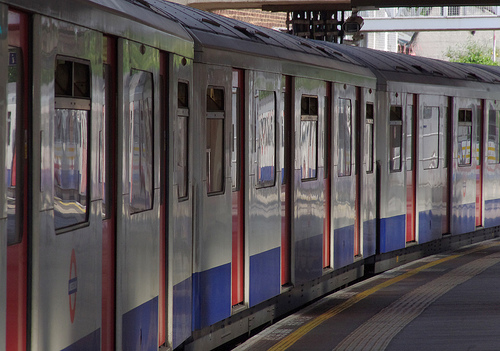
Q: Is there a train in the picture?
A: Yes, there is a train.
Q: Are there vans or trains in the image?
A: Yes, there is a train.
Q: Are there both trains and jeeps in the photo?
A: No, there is a train but no jeeps.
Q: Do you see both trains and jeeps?
A: No, there is a train but no jeeps.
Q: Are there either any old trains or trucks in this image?
A: Yes, there is an old train.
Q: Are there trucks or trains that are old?
A: Yes, the train is old.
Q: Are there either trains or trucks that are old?
A: Yes, the train is old.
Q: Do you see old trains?
A: Yes, there is an old train.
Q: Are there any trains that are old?
A: Yes, there is a train that is old.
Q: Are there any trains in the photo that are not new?
A: Yes, there is a old train.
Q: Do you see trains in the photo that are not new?
A: Yes, there is a old train.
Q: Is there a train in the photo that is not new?
A: Yes, there is a old train.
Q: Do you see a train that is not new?
A: Yes, there is a old train.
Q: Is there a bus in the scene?
A: No, there are no buses.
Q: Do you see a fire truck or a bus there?
A: No, there are no buses or fire trucks.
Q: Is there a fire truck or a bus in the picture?
A: No, there are no buses or fire trucks.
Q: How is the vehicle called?
A: The vehicle is a train.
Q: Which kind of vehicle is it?
A: The vehicle is a train.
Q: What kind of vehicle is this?
A: This is a train.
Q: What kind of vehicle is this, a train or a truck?
A: This is a train.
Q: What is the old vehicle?
A: The vehicle is a train.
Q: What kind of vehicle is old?
A: The vehicle is a train.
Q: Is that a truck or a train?
A: That is a train.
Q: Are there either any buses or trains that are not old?
A: No, there is a train but it is old.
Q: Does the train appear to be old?
A: Yes, the train is old.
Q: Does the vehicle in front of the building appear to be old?
A: Yes, the train is old.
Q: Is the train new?
A: No, the train is old.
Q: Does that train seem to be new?
A: No, the train is old.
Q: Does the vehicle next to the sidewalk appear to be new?
A: No, the train is old.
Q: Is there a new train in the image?
A: No, there is a train but it is old.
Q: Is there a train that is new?
A: No, there is a train but it is old.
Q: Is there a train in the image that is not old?
A: No, there is a train but it is old.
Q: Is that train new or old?
A: The train is old.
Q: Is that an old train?
A: Yes, that is an old train.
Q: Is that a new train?
A: No, that is an old train.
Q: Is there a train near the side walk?
A: Yes, there is a train near the side walk.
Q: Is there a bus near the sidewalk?
A: No, there is a train near the sidewalk.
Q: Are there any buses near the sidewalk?
A: No, there is a train near the sidewalk.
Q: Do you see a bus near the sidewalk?
A: No, there is a train near the sidewalk.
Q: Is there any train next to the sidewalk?
A: Yes, there is a train next to the sidewalk.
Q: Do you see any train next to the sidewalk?
A: Yes, there is a train next to the sidewalk.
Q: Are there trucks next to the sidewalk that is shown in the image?
A: No, there is a train next to the sidewalk.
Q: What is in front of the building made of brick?
A: The train is in front of the building.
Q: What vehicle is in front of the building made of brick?
A: The vehicle is a train.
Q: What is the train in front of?
A: The train is in front of the building.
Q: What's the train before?
A: The train is in front of the building.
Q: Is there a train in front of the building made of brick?
A: Yes, there is a train in front of the building.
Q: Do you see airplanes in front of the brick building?
A: No, there is a train in front of the building.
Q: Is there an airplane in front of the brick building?
A: No, there is a train in front of the building.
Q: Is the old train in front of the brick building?
A: Yes, the train is in front of the building.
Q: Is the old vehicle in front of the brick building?
A: Yes, the train is in front of the building.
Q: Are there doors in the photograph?
A: Yes, there is a door.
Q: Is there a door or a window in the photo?
A: Yes, there is a door.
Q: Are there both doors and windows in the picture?
A: Yes, there are both a door and a window.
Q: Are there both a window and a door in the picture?
A: Yes, there are both a door and a window.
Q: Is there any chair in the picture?
A: No, there are no chairs.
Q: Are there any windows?
A: Yes, there is a window.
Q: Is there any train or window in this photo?
A: Yes, there is a window.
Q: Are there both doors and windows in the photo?
A: Yes, there are both a window and a door.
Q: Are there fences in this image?
A: No, there are no fences.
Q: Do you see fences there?
A: No, there are no fences.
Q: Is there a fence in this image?
A: No, there are no fences.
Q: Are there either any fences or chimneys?
A: No, there are no fences or chimneys.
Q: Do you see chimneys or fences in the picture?
A: No, there are no fences or chimneys.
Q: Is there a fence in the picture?
A: No, there are no fences.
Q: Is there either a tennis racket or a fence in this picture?
A: No, there are no fences or rackets.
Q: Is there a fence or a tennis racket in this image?
A: No, there are no fences or rackets.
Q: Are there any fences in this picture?
A: No, there are no fences.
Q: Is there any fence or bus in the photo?
A: No, there are no fences or buses.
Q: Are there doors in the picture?
A: Yes, there is a door.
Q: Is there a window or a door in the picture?
A: Yes, there is a door.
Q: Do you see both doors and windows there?
A: Yes, there are both a door and a window.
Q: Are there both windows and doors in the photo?
A: Yes, there are both a door and a window.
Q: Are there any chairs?
A: No, there are no chairs.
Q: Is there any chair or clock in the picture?
A: No, there are no chairs or clocks.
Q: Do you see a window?
A: Yes, there is a window.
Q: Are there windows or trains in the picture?
A: Yes, there is a window.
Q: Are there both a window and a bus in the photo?
A: No, there is a window but no buses.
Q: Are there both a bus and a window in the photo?
A: No, there is a window but no buses.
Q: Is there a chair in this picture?
A: No, there are no chairs.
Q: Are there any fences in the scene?
A: No, there are no fences.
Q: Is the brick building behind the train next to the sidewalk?
A: Yes, the building is behind the train.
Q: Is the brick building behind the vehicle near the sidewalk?
A: Yes, the building is behind the train.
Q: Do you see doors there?
A: Yes, there are doors.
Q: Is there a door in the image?
A: Yes, there are doors.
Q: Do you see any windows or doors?
A: Yes, there are doors.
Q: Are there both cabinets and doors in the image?
A: No, there are doors but no cabinets.